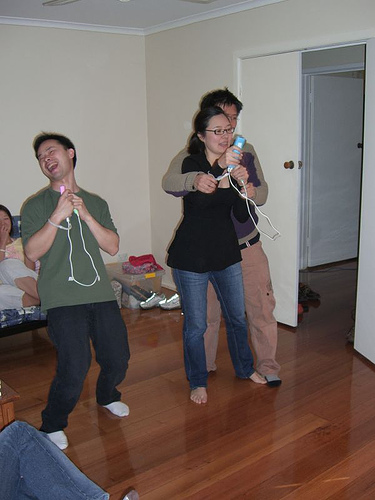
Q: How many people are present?
A: Four.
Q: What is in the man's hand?
A: A wii controller.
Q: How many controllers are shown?
A: Two.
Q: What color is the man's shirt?
A: Green.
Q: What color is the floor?
A: Brown.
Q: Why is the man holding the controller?
A: To play a game.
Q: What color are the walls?
A: White.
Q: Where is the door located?
A: On the right.